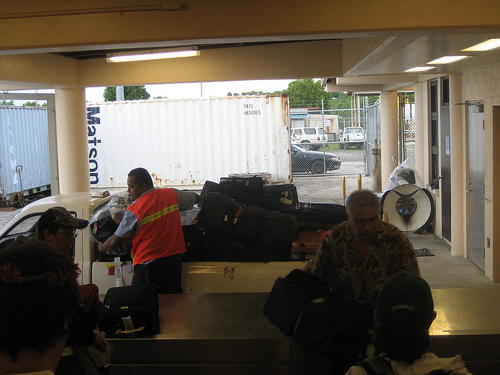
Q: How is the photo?
A: Clear.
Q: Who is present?
A: Worker.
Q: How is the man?
A: Motionless.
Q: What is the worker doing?
A: Loading.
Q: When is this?
A: Daytime.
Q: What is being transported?
A: Bags.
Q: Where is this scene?
A: At luggage retrieval.